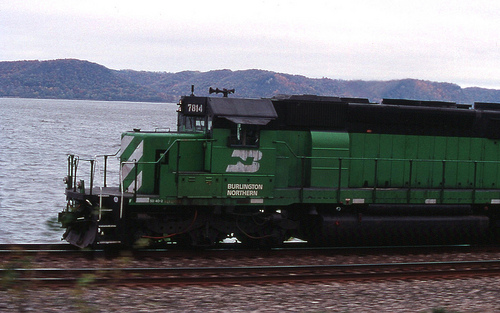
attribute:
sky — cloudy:
[4, 3, 482, 84]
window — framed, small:
[174, 107, 213, 137]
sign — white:
[225, 148, 267, 172]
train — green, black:
[57, 84, 498, 254]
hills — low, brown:
[0, 54, 499, 101]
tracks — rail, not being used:
[0, 240, 498, 301]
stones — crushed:
[9, 286, 499, 311]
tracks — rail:
[7, 239, 498, 309]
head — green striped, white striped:
[115, 125, 148, 205]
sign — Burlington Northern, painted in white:
[219, 148, 272, 203]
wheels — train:
[128, 205, 298, 252]